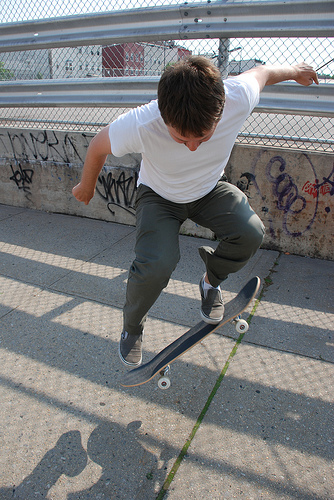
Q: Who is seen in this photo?
A: A boy.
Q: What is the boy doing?
A: Skateboarding.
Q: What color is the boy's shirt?
A: White.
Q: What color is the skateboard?
A: Black and brown.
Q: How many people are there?
A: One.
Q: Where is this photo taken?
A: On a sidewalk.